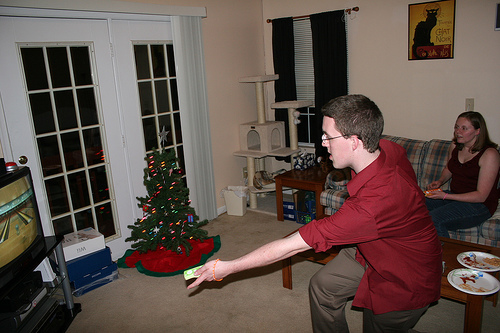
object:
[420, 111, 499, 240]
woman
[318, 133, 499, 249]
couch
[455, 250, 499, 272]
plates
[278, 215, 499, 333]
table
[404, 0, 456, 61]
drawing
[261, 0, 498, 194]
wall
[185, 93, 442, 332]
boy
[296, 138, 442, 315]
shirt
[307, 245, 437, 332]
pants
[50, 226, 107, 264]
box